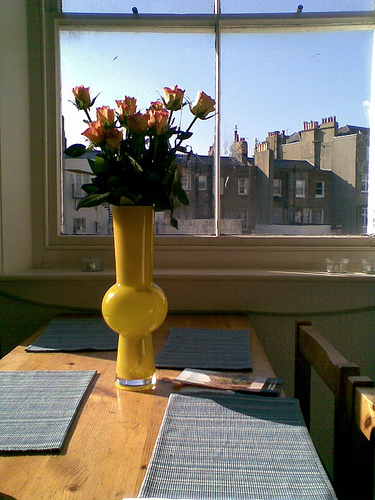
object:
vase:
[101, 208, 169, 394]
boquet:
[63, 82, 220, 230]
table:
[0, 320, 337, 500]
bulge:
[102, 281, 167, 337]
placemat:
[138, 391, 340, 500]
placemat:
[155, 326, 252, 371]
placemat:
[0, 370, 96, 455]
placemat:
[26, 319, 118, 353]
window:
[26, 0, 374, 268]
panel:
[219, 27, 375, 238]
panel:
[57, 25, 215, 237]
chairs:
[332, 375, 375, 500]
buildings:
[62, 143, 165, 234]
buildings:
[164, 133, 333, 233]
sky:
[218, 29, 371, 115]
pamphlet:
[172, 367, 283, 397]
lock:
[131, 4, 143, 18]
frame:
[50, 13, 374, 30]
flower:
[70, 83, 91, 111]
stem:
[85, 110, 93, 123]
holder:
[324, 257, 349, 273]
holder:
[79, 256, 104, 271]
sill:
[0, 267, 375, 315]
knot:
[65, 484, 82, 494]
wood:
[1, 462, 114, 498]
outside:
[60, 1, 375, 234]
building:
[266, 113, 371, 233]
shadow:
[154, 377, 305, 427]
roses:
[189, 89, 217, 121]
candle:
[88, 259, 96, 270]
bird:
[111, 54, 120, 63]